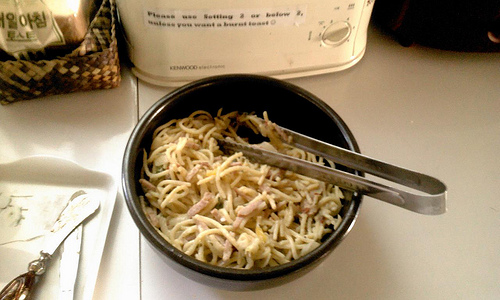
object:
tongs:
[215, 114, 448, 217]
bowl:
[121, 70, 369, 282]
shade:
[0, 63, 138, 162]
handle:
[322, 20, 352, 46]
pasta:
[139, 105, 350, 270]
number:
[330, 19, 334, 24]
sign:
[142, 5, 307, 31]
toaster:
[113, 0, 381, 89]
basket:
[0, 0, 125, 108]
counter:
[0, 23, 497, 299]